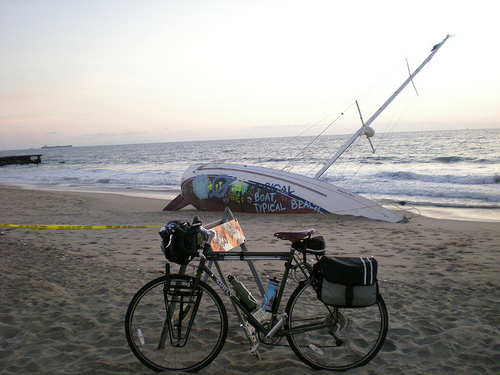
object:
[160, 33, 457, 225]
sailboat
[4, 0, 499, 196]
blue sky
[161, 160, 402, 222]
boat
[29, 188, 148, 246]
beach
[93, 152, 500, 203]
waves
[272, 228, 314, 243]
bicycle seat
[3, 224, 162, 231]
caution tape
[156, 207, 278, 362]
post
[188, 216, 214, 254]
handlebars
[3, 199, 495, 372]
sand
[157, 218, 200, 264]
basket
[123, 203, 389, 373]
bicycle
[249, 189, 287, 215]
graffiti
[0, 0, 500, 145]
clouds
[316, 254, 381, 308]
bag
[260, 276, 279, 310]
bottle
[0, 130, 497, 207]
ocean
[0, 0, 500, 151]
sky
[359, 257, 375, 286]
stripes